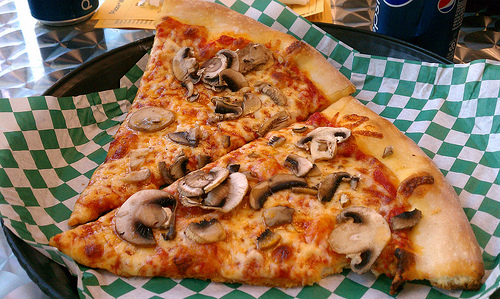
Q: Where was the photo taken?
A: Restaurant.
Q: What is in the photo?
A: Pizza.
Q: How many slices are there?
A: Two.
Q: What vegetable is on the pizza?
A: Mushrooms.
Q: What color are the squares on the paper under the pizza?
A: Green and white.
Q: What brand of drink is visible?
A: Pepsi.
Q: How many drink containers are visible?
A: Two.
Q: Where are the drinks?
A: Behind the pizza.